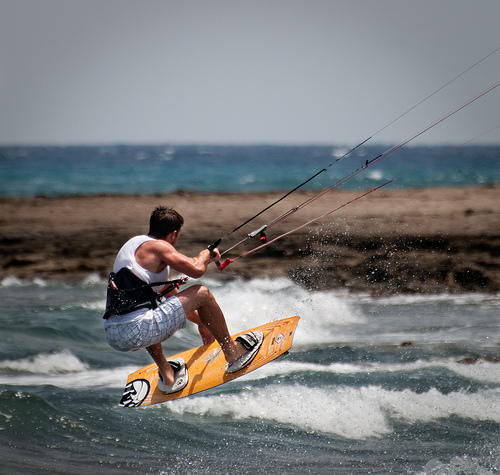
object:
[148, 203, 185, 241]
hair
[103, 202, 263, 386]
man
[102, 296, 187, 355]
shorts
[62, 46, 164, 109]
air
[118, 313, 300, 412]
board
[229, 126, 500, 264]
lines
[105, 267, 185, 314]
harness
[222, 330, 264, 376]
foot straps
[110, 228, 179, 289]
shirt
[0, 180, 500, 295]
shore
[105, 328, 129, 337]
stripes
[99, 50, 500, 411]
parasailing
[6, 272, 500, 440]
waves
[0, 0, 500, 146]
sky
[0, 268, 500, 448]
foam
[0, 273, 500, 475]
ocean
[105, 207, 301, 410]
skiing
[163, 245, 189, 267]
muscles